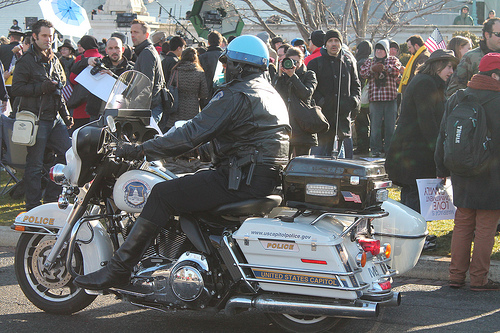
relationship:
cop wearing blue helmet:
[72, 32, 295, 289] [217, 35, 278, 70]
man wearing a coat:
[70, 33, 295, 294] [140, 73, 294, 182]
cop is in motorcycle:
[67, 32, 294, 289] [8, 70, 435, 332]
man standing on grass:
[70, 33, 295, 294] [389, 177, 498, 253]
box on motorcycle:
[277, 152, 393, 214] [8, 70, 435, 332]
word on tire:
[21, 215, 55, 227] [12, 227, 103, 316]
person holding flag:
[381, 48, 462, 253] [423, 23, 447, 57]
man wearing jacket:
[70, 33, 295, 294] [132, 73, 293, 173]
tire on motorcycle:
[16, 227, 93, 314] [8, 70, 435, 332]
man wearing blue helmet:
[70, 33, 295, 294] [217, 34, 271, 71]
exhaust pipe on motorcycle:
[229, 290, 396, 313] [8, 70, 435, 332]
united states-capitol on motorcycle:
[246, 270, 358, 289] [14, 105, 440, 312]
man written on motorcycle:
[70, 33, 295, 294] [8, 70, 435, 332]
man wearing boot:
[70, 33, 295, 294] [73, 216, 158, 290]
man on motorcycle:
[70, 33, 295, 294] [8, 70, 435, 332]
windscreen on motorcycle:
[105, 70, 155, 112] [8, 70, 435, 332]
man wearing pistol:
[70, 33, 295, 294] [226, 152, 257, 190]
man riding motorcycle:
[70, 33, 295, 294] [8, 70, 435, 332]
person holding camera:
[381, 48, 462, 253] [281, 58, 293, 69]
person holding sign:
[401, 49, 449, 176] [416, 173, 458, 222]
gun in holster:
[234, 152, 254, 163] [229, 157, 241, 189]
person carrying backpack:
[381, 48, 462, 253] [440, 94, 495, 177]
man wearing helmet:
[197, 34, 285, 221] [214, 30, 273, 71]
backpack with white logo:
[434, 94, 495, 174] [456, 121, 462, 143]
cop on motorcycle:
[67, 32, 294, 289] [8, 70, 435, 332]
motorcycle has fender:
[8, 70, 435, 332] [11, 199, 114, 296]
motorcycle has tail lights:
[27, 123, 437, 327] [362, 223, 404, 266]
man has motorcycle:
[70, 33, 295, 294] [8, 70, 435, 332]